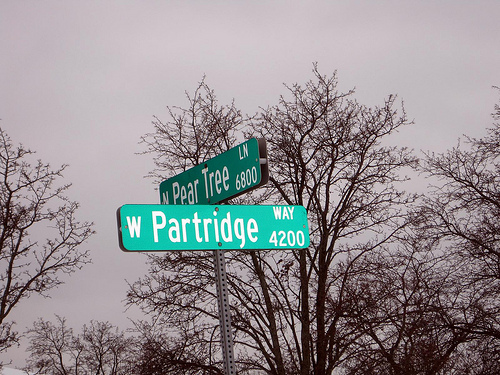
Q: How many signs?
A: Two.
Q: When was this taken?
A: During the daytime.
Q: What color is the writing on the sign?
A: White.